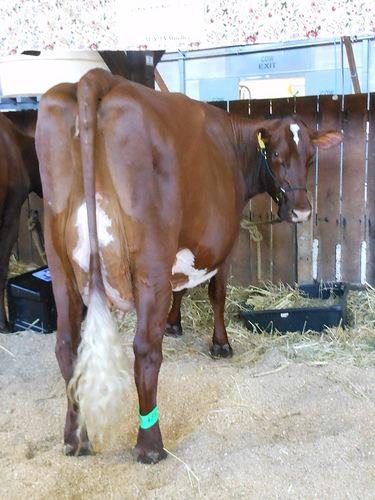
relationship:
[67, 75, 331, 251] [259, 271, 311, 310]
cow eating hay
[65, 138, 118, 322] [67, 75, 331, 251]
tail on cow